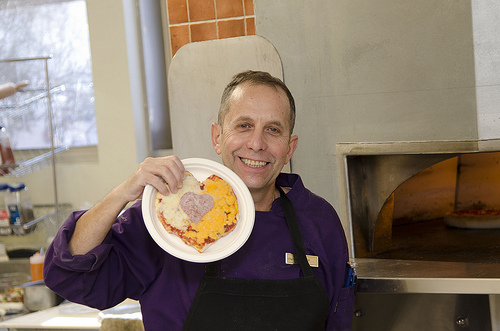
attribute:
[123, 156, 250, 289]
plate — white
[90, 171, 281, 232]
plate — white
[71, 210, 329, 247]
coat — purple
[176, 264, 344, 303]
apron — black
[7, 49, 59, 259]
shelves — metal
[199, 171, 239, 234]
cheese — yellow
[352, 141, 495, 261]
painting — hanging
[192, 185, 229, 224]
meat — heart shaped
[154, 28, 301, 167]
board — rectangular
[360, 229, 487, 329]
oven — hot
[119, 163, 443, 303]
jacket — purple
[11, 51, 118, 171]
window — open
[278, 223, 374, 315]
name tag — gold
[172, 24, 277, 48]
tiles — brown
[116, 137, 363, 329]
pizza — heart shaped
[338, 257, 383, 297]
pens — blue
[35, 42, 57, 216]
rack — metal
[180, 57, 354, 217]
man — smiling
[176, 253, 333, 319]
apron — black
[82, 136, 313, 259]
plate — white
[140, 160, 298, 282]
pizza — heart shaped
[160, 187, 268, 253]
pizza — heart shaped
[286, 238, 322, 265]
name tag — gold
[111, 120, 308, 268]
pizza — heart shaped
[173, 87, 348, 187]
man — smiling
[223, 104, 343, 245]
man — smiling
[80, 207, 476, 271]
shirt — purple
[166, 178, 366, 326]
apron — black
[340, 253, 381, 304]
pen — blue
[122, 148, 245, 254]
plate — white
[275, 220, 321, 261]
name tag — gold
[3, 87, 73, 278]
spices — racked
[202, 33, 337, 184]
man — smiling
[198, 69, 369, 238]
man — smiling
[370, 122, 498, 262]
picture — hanging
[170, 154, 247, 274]
plate — white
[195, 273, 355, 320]
apron — black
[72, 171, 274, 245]
pizza — heart shaped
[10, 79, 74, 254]
stand — metal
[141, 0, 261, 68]
brick — red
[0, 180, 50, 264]
container — clear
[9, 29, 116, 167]
window — bright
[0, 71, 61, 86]
pin — brown